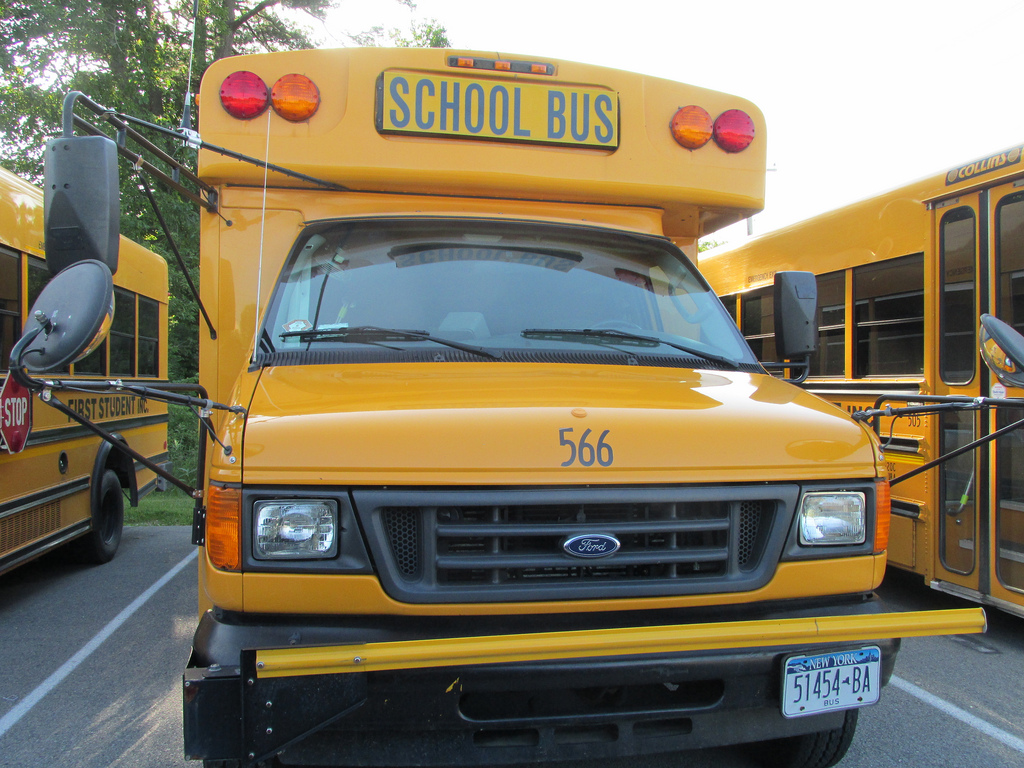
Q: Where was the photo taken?
A: At a bus terminal.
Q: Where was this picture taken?
A: In a bus parking lot.